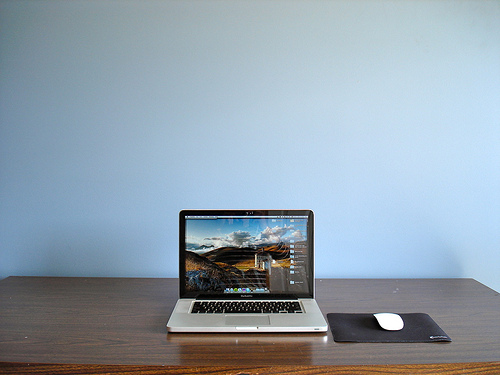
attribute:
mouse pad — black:
[328, 312, 451, 341]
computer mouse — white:
[373, 312, 405, 331]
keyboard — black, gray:
[167, 295, 328, 332]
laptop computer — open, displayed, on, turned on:
[167, 208, 329, 334]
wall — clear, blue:
[0, 0, 499, 277]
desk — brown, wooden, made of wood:
[0, 280, 499, 372]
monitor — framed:
[179, 208, 314, 296]